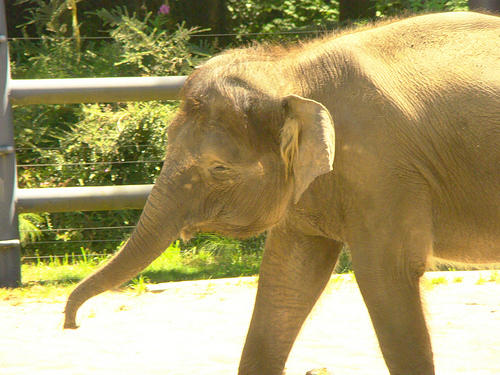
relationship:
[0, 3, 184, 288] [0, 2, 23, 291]
fence has post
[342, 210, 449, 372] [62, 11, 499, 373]
leg of elephant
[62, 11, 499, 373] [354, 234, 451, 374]
elephant has leg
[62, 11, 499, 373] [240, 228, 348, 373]
elephant has leg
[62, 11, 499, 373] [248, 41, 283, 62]
elephant has hair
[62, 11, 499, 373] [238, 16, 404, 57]
elephant has hair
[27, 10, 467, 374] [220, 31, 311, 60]
elephant has hair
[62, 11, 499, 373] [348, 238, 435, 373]
elephant has leg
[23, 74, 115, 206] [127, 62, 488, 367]
fence behind elephant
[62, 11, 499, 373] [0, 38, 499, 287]
elephant inside pen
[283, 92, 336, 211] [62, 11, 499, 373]
ear on elephant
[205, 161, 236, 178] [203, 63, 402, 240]
eye on elephants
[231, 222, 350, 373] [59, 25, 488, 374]
leg on elephants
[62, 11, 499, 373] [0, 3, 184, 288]
elephant walking beside fence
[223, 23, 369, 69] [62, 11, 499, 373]
hair on elephant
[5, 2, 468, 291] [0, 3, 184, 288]
green area beyond fence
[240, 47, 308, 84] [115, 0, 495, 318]
hair on top of elephant